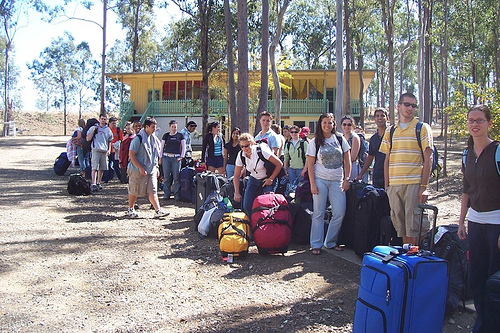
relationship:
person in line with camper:
[380, 88, 435, 249] [307, 108, 356, 253]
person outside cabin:
[380, 88, 435, 249] [102, 67, 379, 136]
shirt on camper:
[372, 115, 434, 196] [307, 108, 356, 253]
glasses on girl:
[467, 117, 485, 124] [456, 102, 499, 332]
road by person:
[1, 137, 438, 332] [380, 88, 435, 249]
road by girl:
[1, 137, 438, 332] [456, 102, 499, 332]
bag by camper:
[218, 206, 251, 259] [307, 108, 356, 253]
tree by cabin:
[28, 28, 84, 136] [102, 67, 379, 136]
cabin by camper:
[102, 67, 379, 136] [307, 108, 356, 253]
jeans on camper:
[305, 178, 348, 251] [307, 108, 356, 253]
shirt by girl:
[372, 115, 434, 196] [456, 102, 499, 332]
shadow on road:
[61, 213, 131, 225] [1, 137, 438, 332]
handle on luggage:
[416, 203, 440, 249] [353, 242, 449, 333]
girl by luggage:
[456, 102, 499, 332] [353, 242, 449, 333]